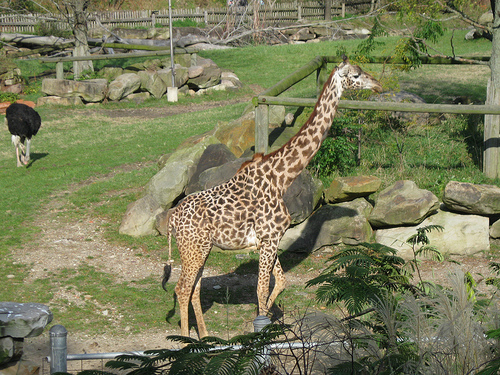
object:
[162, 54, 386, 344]
giraffe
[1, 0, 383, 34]
fence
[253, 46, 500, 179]
railing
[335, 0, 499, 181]
tree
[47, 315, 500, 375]
fence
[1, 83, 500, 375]
dirt path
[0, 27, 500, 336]
grass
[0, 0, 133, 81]
tree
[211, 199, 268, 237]
markings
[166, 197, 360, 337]
shadow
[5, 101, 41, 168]
animals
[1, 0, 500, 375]
enclosure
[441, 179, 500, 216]
rocks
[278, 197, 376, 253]
rock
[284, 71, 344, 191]
long neck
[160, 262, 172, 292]
tail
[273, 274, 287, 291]
bent knee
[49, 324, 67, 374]
post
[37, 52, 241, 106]
pile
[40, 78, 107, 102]
large rocks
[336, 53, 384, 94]
head